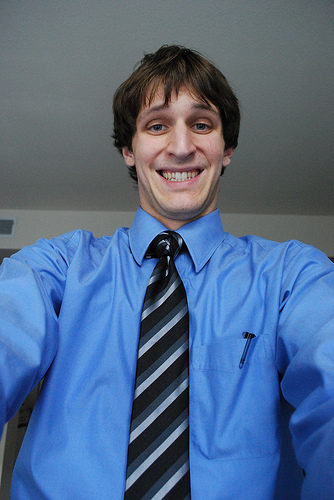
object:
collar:
[126, 203, 225, 275]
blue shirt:
[0, 206, 333, 498]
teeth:
[160, 169, 200, 182]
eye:
[189, 116, 214, 134]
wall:
[277, 136, 332, 236]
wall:
[209, 215, 333, 244]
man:
[0, 45, 332, 499]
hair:
[109, 43, 240, 192]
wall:
[3, 159, 118, 236]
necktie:
[123, 227, 195, 476]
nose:
[165, 117, 197, 162]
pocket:
[192, 328, 281, 462]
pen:
[238, 327, 255, 370]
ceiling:
[2, 2, 333, 212]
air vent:
[0, 216, 14, 235]